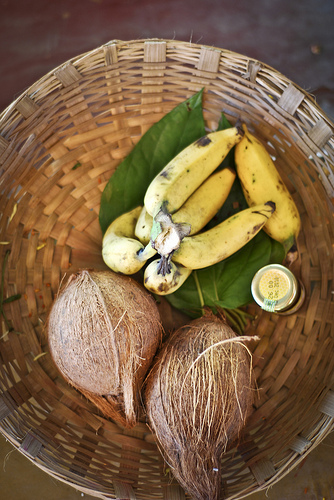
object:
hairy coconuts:
[44, 258, 169, 430]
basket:
[1, 29, 334, 500]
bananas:
[162, 198, 276, 272]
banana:
[233, 114, 303, 268]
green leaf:
[96, 87, 208, 245]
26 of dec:
[267, 290, 274, 301]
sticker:
[261, 296, 278, 314]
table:
[0, 31, 334, 500]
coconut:
[43, 259, 165, 420]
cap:
[250, 262, 299, 312]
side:
[88, 68, 126, 115]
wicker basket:
[41, 43, 293, 158]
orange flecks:
[269, 1, 332, 65]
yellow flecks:
[15, 193, 60, 258]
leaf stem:
[125, 164, 145, 188]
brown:
[81, 296, 117, 344]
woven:
[83, 60, 135, 109]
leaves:
[187, 110, 259, 296]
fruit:
[227, 117, 305, 260]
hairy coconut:
[138, 307, 268, 500]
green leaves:
[154, 169, 274, 321]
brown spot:
[192, 135, 212, 149]